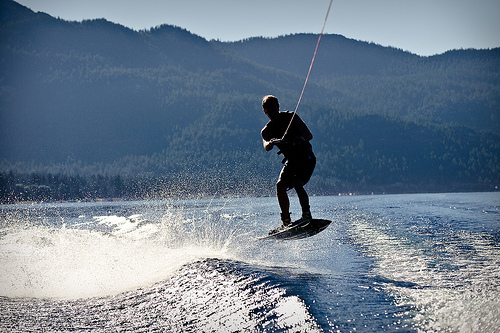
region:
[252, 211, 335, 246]
a surf board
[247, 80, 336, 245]
a person surfing in water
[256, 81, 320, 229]
a person wearing a pair of shorts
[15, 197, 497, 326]
a body of water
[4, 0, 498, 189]
some hills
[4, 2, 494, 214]
green vegetation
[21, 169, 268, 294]
splashed water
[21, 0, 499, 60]
a grey sky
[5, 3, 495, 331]
it is a daytime scene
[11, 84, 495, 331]
a person in an ocean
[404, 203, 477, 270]
Water is blue color.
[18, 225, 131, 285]
water is splashing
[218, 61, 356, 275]
One man is wake-boarding.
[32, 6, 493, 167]
Mountain is seen behind the water.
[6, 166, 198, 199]
Trees are seen behind the water.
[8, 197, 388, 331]
Waves are white color.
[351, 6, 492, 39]
Sky is blue color.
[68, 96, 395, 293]
Sunlight reflection is seen in water.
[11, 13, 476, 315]
Day time picture.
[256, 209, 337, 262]
One wake board is seen.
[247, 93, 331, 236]
A male surfing on the water.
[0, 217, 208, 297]
The white sea foam.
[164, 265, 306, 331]
The glaring reflection of the sun.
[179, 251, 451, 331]
A small wave in the water.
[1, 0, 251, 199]
An area full of trees.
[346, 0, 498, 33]
The clear dark blue sky.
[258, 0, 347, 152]
A man holding a purple string.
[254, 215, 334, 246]
The dark surf board.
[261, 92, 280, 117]
The surfers short hair.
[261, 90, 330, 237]
The dark silhouette-like image of the man.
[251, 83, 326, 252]
shadow of a jet skier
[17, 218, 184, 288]
white rush of wave water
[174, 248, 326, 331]
dark blue wave colliding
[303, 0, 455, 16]
clear blue sky above mountains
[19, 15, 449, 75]
rolling mountain tops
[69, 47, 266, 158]
dark green rolling forest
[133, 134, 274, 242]
splash of small water beads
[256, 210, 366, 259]
black surfboard jet ski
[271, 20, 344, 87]
wire attached to boat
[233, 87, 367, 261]
man jet skiing in the water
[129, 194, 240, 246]
water droplets spraying in the air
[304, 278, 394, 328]
sunlight reflecting on the water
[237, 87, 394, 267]
a man surfing in the ocean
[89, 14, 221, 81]
a hill on the horizon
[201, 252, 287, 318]
a smooth blue wave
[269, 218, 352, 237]
a surfboard supporting a person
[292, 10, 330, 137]
a rope tied a man's hand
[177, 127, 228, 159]
a thick forest of trees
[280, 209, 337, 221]
straps on surfing boots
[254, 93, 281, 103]
hair growing on a head